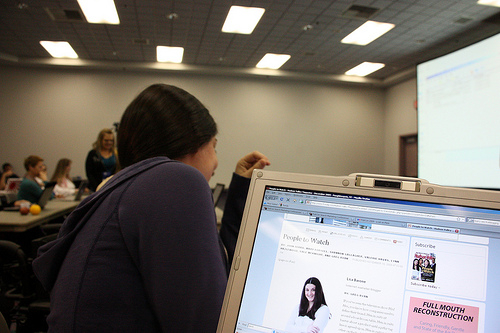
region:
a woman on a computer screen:
[274, 266, 344, 331]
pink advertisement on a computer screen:
[402, 293, 482, 331]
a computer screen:
[202, 160, 485, 332]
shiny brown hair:
[113, 70, 220, 177]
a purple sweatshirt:
[38, 158, 230, 328]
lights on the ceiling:
[5, 3, 478, 97]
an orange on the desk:
[25, 199, 45, 220]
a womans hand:
[230, 148, 273, 185]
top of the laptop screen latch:
[355, 173, 417, 197]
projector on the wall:
[411, 40, 498, 180]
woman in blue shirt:
[61, 82, 246, 331]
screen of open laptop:
[248, 170, 486, 331]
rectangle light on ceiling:
[221, 5, 266, 37]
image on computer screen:
[261, 229, 490, 331]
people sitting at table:
[20, 156, 74, 203]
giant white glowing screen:
[415, 35, 498, 187]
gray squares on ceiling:
[402, 5, 450, 44]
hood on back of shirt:
[33, 197, 98, 287]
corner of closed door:
[398, 132, 415, 177]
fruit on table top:
[17, 203, 45, 220]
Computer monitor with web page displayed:
[213, 166, 498, 332]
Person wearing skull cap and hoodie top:
[59, 82, 248, 332]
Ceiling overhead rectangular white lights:
[37, 1, 397, 78]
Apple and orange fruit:
[17, 203, 42, 218]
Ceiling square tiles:
[0, 1, 499, 85]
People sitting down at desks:
[0, 156, 92, 227]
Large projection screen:
[414, 32, 499, 189]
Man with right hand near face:
[14, 153, 51, 209]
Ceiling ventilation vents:
[337, 0, 474, 28]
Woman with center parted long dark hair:
[296, 275, 328, 320]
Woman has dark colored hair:
[89, 80, 231, 197]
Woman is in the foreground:
[27, 68, 270, 330]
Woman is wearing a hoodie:
[16, 138, 227, 332]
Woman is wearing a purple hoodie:
[26, 150, 228, 332]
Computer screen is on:
[226, 150, 498, 332]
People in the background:
[2, 116, 127, 208]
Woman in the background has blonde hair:
[73, 118, 120, 189]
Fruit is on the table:
[17, 192, 45, 222]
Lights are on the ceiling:
[17, 2, 426, 95]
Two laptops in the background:
[7, 148, 89, 212]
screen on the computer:
[234, 186, 498, 331]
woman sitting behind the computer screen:
[39, 81, 268, 332]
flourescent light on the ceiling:
[254, 49, 292, 80]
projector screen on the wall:
[415, 29, 499, 192]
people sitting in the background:
[0, 126, 128, 207]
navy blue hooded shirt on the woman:
[34, 163, 255, 331]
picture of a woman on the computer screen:
[292, 274, 332, 331]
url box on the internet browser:
[307, 196, 467, 223]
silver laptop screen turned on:
[211, 161, 497, 331]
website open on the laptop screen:
[229, 179, 497, 326]